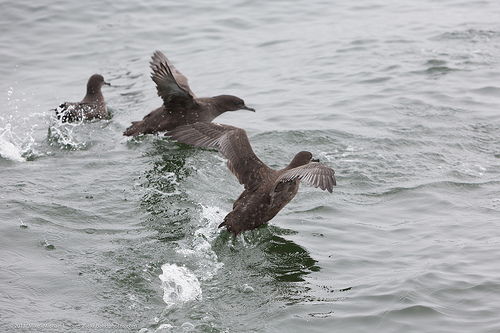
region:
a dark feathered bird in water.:
[157, 119, 340, 249]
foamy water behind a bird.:
[140, 194, 260, 322]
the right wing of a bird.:
[261, 151, 341, 196]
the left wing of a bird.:
[173, 119, 277, 189]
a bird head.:
[276, 149, 321, 174]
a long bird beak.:
[237, 102, 258, 119]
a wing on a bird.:
[147, 41, 194, 112]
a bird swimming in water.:
[49, 68, 120, 148]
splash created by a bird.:
[1, 131, 91, 162]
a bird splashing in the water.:
[137, 116, 357, 313]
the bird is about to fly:
[156, 110, 321, 221]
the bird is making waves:
[152, 198, 274, 313]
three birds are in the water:
[32, 25, 339, 220]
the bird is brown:
[188, 120, 340, 226]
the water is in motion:
[0, 90, 92, 172]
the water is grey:
[338, 47, 447, 304]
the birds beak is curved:
[230, 89, 262, 116]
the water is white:
[138, 250, 221, 305]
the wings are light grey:
[169, 105, 344, 195]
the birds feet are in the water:
[195, 203, 267, 255]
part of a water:
[336, 45, 402, 99]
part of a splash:
[169, 277, 206, 328]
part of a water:
[328, 219, 395, 301]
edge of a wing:
[292, 175, 332, 202]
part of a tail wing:
[221, 199, 281, 264]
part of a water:
[374, 264, 423, 326]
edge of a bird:
[220, 210, 283, 225]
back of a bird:
[251, 167, 271, 198]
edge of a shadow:
[281, 217, 332, 284]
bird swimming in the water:
[56, 74, 114, 120]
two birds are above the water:
[122, 50, 339, 248]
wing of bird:
[163, 121, 265, 194]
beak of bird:
[242, 104, 259, 114]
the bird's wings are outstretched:
[164, 118, 338, 196]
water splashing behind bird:
[0, 103, 87, 160]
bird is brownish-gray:
[165, 116, 338, 241]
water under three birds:
[1, 0, 495, 331]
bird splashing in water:
[163, 123, 340, 240]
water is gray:
[2, 2, 499, 331]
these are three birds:
[62, 65, 329, 262]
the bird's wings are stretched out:
[136, 45, 348, 192]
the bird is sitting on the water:
[52, 68, 119, 120]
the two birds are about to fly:
[144, 56, 336, 236]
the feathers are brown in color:
[246, 172, 272, 197]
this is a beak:
[238, 100, 258, 117]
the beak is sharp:
[243, 96, 260, 121]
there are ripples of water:
[336, 125, 486, 190]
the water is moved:
[163, 230, 253, 326]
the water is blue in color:
[348, 215, 424, 288]